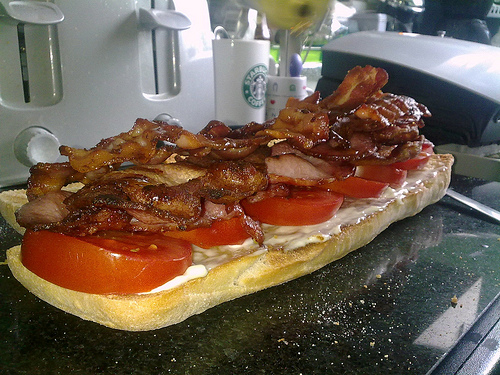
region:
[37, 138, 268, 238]
Bacon on a sandwich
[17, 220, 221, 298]
Red, slices tomatoe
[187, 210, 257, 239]
Sliced piece of tomatoe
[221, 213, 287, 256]
Mayo on a piece of bread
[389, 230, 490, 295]
Black counter with crumbs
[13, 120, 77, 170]
White dial on a toaster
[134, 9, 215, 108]
White handle on a toaster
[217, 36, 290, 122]
White Starbucks mug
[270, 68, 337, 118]
White mug on a counter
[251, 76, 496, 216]
Bacon and tomatoe on bread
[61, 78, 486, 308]
a piled high sandwich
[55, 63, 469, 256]
lots of bacon on top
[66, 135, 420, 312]
thick slices of tomoto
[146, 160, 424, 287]
mayonaise on the bottom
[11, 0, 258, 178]
a white toaster behind sandwich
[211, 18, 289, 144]
a Starbuck's coffee mug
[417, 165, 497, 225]
part of a utensil next to sandwich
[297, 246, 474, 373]
crumbs on the counter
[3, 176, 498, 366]
black marble counter under sandwich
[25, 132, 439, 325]
a bacon and tomato sandwich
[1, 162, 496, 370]
black counter top under sandwich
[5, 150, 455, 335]
italian bread on counter top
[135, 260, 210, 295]
white mayo on bread under tomato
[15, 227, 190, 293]
thick sliced tomato on mayo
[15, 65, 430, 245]
pile of bacon on tomato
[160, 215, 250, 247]
sliced tomato next to tomato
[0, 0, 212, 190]
white toaster behind sandwich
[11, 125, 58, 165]
white knob on toaster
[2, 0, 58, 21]
gray lever above white knob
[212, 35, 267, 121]
white mug with logo next to toaster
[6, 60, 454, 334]
Loaded sub type sandwhich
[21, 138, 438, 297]
Row of tomatoes on sandwich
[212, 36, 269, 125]
White coffee mug with Starbucks logo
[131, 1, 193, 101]
White toaster lever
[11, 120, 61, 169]
White knob dial on toaster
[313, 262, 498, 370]
Crumbs gathered on counter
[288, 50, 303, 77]
Top of purple spoon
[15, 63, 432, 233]
Heap of cooked bacon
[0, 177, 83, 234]
Slice for sandwich top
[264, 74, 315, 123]
Small white coffee cup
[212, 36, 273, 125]
white mug behind sandwich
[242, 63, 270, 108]
green starbucks logo printed on mug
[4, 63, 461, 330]
large open face sandwich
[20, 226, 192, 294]
red tomato slice on top of sandwich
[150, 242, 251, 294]
white mayonnaise under tomato slice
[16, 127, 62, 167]
round knob on toaster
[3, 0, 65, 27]
white lever attached to toaster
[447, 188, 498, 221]
silver utensil handle on counter top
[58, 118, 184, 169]
crunchy bacon slice